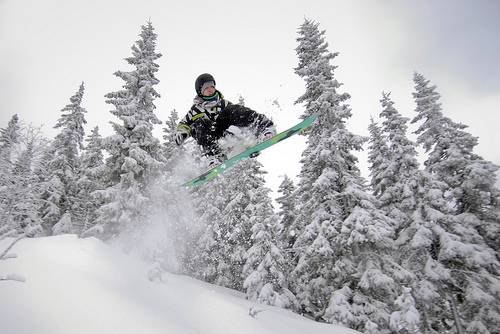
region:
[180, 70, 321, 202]
snowboarder in the air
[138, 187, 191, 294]
snow in the air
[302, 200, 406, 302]
snow on the trees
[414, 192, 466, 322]
the trees are pine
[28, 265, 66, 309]
the snow is smooth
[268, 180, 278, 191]
the sky is white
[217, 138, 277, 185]
the snowboard is green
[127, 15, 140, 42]
top of the tree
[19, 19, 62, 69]
the sky is cloudy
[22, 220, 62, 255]
top of the hill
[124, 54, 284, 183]
this is a person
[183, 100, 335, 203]
this is a ski board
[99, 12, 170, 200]
this is a tree with ice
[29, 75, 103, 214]
this is a tree with ice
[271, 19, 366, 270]
this is a tree with ice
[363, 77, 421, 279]
this is a tree with ice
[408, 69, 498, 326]
this is a tree with ice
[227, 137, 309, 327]
this is a tree with ice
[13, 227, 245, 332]
this is a ice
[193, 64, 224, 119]
this is a head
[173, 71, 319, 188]
Person on snow board in mid air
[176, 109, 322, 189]
Green snow board in mid air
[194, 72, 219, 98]
head of the snow boarder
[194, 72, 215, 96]
black bonnet on the head of the snow boarder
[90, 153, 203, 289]
Snow trail caused by the snow boarder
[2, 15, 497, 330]
Pine trees covered with snow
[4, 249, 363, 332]
Snowy slope near the pine trees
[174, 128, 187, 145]
right hand of the snow boarder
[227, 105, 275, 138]
left leg of the snow boarder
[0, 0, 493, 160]
Cloudy weather in the sky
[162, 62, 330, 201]
Snowboarder in the air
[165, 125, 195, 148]
Right hand of snowboarder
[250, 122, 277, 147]
Left boot of snowboarder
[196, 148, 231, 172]
Right boot of snowboarder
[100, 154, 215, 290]
Snow misting in the air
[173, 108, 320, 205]
Snowboard rider is riding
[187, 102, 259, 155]
Black pants of snowboarder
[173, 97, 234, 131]
Black, white, and green jacket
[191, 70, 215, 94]
Black and gray hat of boarder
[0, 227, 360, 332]
White snow on the ground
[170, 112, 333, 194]
Person on a board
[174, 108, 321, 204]
Person is on a board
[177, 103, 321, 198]
Person on a green board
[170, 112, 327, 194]
Person is on a green board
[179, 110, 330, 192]
Person on a snowboard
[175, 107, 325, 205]
Person is on a snowboard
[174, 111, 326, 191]
Person on a green snowboard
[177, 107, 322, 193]
Person is on a green snowboard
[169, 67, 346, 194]
Person in the air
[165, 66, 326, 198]
Person is in the air